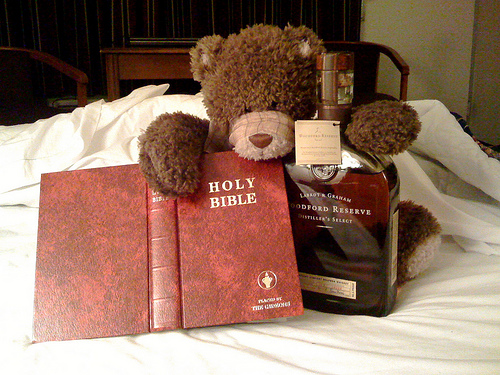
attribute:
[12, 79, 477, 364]
sheet — white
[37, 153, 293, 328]
bible — hardcover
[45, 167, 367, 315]
bible — red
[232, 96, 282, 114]
eyes — black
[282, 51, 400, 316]
bottle — nice, large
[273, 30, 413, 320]
bottle — bourbon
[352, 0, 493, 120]
walls — beige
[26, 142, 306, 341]
bible — gideon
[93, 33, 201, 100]
table — wooden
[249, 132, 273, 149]
nose — brown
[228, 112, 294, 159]
nose — plaid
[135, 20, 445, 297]
teddy bear — brown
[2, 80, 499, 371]
sheets — white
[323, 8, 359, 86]
curtains — dark